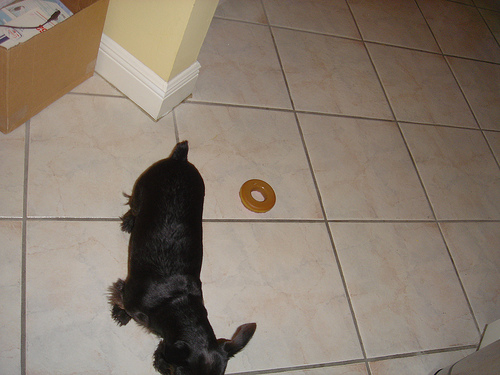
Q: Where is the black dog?
A: On the floor.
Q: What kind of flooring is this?
A: White tile with gray grout.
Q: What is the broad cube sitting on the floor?
A: A cardboard box.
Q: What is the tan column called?
A: It is called a wall.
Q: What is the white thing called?
A: The white thing is called trim.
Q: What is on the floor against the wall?
A: A cardboard box.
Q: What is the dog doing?
A: The dogging is standing.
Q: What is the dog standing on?
A: The dog is standing on the floor.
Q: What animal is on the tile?
A: A dog.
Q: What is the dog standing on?
A: A tile floor.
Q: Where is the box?
A: Next to the wall.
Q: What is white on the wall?
A: The baseboard moulding.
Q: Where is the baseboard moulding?
A: The bottom of the wall.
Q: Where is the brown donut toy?
A: On the tile.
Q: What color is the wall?
A: Yellow.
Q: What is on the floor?
A: A dog toy.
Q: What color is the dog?
A: Black.